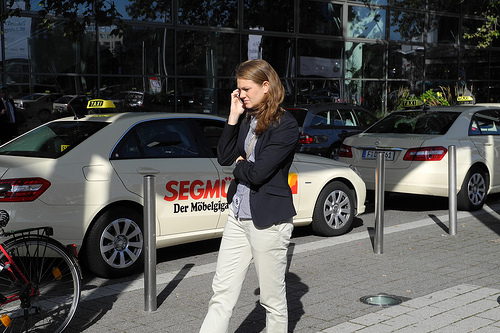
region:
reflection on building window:
[5, 2, 482, 122]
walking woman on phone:
[201, 61, 298, 331]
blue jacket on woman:
[219, 109, 299, 230]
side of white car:
[0, 108, 365, 275]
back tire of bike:
[2, 228, 79, 331]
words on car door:
[163, 175, 230, 216]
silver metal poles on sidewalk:
[142, 143, 457, 313]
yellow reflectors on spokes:
[2, 266, 66, 327]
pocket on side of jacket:
[265, 185, 292, 215]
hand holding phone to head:
[227, 88, 244, 124]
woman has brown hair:
[211, 50, 296, 111]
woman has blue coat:
[195, 85, 305, 242]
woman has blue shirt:
[194, 90, 271, 208]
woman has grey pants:
[187, 218, 287, 329]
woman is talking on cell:
[221, 67, 279, 201]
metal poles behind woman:
[90, 151, 202, 319]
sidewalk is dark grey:
[312, 227, 487, 308]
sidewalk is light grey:
[408, 264, 490, 331]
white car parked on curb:
[52, 83, 392, 255]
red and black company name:
[135, 168, 265, 223]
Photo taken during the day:
[8, 14, 469, 326]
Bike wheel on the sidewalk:
[0, 228, 90, 326]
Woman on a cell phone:
[202, 57, 309, 326]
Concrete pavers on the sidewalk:
[81, 230, 496, 327]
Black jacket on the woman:
[221, 99, 305, 228]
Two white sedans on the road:
[5, 71, 485, 294]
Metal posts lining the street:
[140, 145, 470, 315]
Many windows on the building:
[6, 20, 498, 145]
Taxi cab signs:
[84, 88, 480, 106]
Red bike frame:
[0, 246, 40, 304]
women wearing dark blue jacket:
[195, 57, 300, 331]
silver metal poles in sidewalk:
[143, 144, 455, 311]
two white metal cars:
[1, 95, 499, 278]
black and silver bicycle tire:
[0, 235, 82, 331]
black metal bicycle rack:
[2, 224, 54, 294]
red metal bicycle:
[0, 210, 83, 331]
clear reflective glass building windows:
[1, 0, 499, 145]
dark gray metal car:
[281, 102, 379, 159]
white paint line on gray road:
[1, 205, 499, 320]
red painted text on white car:
[163, 176, 233, 201]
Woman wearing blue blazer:
[193, 55, 300, 331]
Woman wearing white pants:
[195, 56, 299, 331]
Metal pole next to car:
[140, 171, 161, 310]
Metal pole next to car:
[371, 148, 387, 257]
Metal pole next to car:
[445, 142, 460, 236]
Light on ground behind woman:
[360, 293, 400, 309]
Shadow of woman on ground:
[231, 265, 308, 332]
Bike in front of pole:
[0, 205, 89, 329]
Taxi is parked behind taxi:
[0, 95, 367, 278]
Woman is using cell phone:
[194, 58, 305, 332]